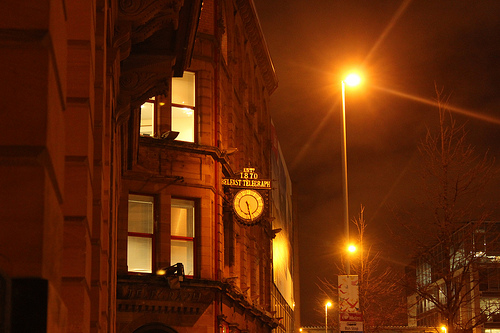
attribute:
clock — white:
[227, 187, 267, 224]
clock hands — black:
[243, 200, 254, 224]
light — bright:
[324, 57, 409, 118]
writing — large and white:
[338, 312, 361, 319]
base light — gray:
[151, 243, 335, 286]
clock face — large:
[193, 131, 286, 230]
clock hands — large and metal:
[245, 195, 250, 264]